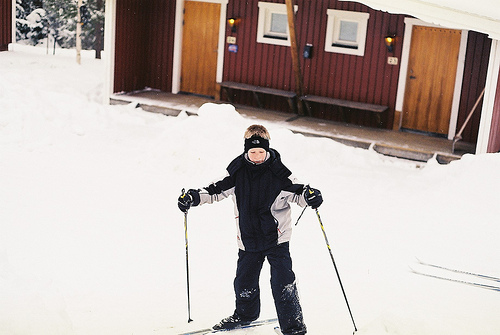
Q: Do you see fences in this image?
A: No, there are no fences.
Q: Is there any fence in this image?
A: No, there are no fences.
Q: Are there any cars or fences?
A: No, there are no fences or cars.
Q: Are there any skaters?
A: No, there are no skaters.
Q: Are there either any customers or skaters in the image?
A: No, there are no skaters or customers.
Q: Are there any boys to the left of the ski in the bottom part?
A: Yes, there is a boy to the left of the ski.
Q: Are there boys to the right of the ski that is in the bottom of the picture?
A: No, the boy is to the left of the ski.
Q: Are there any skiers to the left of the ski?
A: No, there is a boy to the left of the ski.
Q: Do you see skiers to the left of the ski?
A: No, there is a boy to the left of the ski.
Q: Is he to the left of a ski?
A: Yes, the boy is to the left of a ski.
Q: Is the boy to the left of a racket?
A: No, the boy is to the left of a ski.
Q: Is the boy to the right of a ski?
A: No, the boy is to the left of a ski.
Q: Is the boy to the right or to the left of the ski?
A: The boy is to the left of the ski.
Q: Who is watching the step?
A: The boy is watching the step.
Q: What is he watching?
A: The boy is watching the step.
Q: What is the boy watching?
A: The boy is watching the step.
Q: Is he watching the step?
A: Yes, the boy is watching the step.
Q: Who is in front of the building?
A: The boy is in front of the building.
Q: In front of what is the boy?
A: The boy is in front of the building.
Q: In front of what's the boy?
A: The boy is in front of the building.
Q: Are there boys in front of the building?
A: Yes, there is a boy in front of the building.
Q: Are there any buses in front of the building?
A: No, there is a boy in front of the building.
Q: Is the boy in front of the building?
A: Yes, the boy is in front of the building.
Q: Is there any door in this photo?
A: Yes, there is a door.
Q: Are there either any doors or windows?
A: Yes, there is a door.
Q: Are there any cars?
A: No, there are no cars.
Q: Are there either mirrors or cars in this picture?
A: No, there are no cars or mirrors.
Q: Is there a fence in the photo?
A: No, there are no fences.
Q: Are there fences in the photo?
A: No, there are no fences.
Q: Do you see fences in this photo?
A: No, there are no fences.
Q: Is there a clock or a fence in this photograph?
A: No, there are no fences or clocks.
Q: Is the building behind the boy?
A: Yes, the building is behind the boy.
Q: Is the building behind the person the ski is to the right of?
A: Yes, the building is behind the boy.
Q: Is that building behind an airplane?
A: No, the building is behind the boy.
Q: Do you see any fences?
A: No, there are no fences.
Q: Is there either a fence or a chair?
A: No, there are no fences or chairs.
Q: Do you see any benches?
A: Yes, there is a bench.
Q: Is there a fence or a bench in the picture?
A: Yes, there is a bench.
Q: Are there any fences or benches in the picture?
A: Yes, there is a bench.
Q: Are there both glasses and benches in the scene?
A: No, there is a bench but no glasses.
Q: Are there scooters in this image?
A: No, there are no scooters.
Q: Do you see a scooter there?
A: No, there are no scooters.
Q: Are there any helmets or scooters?
A: No, there are no scooters or helmets.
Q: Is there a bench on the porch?
A: Yes, there is a bench on the porch.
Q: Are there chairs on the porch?
A: No, there is a bench on the porch.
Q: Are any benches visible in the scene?
A: Yes, there is a bench.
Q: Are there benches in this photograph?
A: Yes, there is a bench.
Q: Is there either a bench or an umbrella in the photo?
A: Yes, there is a bench.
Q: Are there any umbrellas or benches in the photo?
A: Yes, there is a bench.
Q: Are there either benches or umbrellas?
A: Yes, there is a bench.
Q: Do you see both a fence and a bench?
A: No, there is a bench but no fences.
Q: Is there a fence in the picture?
A: No, there are no fences.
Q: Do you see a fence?
A: No, there are no fences.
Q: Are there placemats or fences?
A: No, there are no fences or placemats.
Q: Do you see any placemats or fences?
A: No, there are no fences or placemats.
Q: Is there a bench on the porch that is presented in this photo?
A: Yes, there is a bench on the porch.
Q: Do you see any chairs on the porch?
A: No, there is a bench on the porch.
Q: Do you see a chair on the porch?
A: No, there is a bench on the porch.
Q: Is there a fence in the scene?
A: No, there are no fences.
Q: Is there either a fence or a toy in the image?
A: No, there are no fences or toys.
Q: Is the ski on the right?
A: Yes, the ski is on the right of the image.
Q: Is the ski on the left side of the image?
A: No, the ski is on the right of the image.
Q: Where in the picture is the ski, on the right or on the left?
A: The ski is on the right of the image.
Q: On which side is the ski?
A: The ski is on the right of the image.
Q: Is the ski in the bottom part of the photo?
A: Yes, the ski is in the bottom of the image.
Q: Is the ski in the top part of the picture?
A: No, the ski is in the bottom of the image.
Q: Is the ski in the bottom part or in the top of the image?
A: The ski is in the bottom of the image.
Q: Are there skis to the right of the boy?
A: Yes, there is a ski to the right of the boy.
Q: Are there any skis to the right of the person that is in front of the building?
A: Yes, there is a ski to the right of the boy.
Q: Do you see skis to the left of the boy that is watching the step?
A: No, the ski is to the right of the boy.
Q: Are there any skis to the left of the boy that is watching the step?
A: No, the ski is to the right of the boy.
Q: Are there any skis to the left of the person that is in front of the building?
A: No, the ski is to the right of the boy.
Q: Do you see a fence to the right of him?
A: No, there is a ski to the right of the boy.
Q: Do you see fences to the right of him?
A: No, there is a ski to the right of the boy.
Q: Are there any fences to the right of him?
A: No, there is a ski to the right of the boy.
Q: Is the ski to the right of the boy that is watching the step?
A: Yes, the ski is to the right of the boy.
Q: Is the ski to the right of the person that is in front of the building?
A: Yes, the ski is to the right of the boy.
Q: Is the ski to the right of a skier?
A: No, the ski is to the right of the boy.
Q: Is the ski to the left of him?
A: No, the ski is to the right of a boy.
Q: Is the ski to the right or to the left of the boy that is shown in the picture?
A: The ski is to the right of the boy.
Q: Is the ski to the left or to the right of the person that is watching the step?
A: The ski is to the right of the boy.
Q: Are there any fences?
A: No, there are no fences.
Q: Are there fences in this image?
A: No, there are no fences.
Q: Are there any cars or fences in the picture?
A: No, there are no fences or cars.